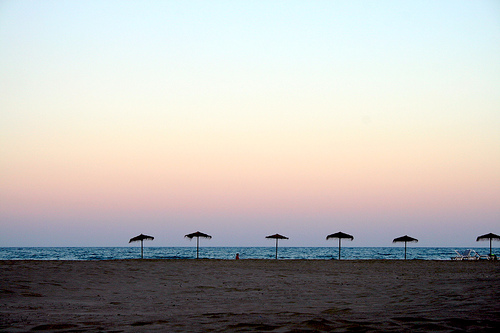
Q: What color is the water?
A: Blue.